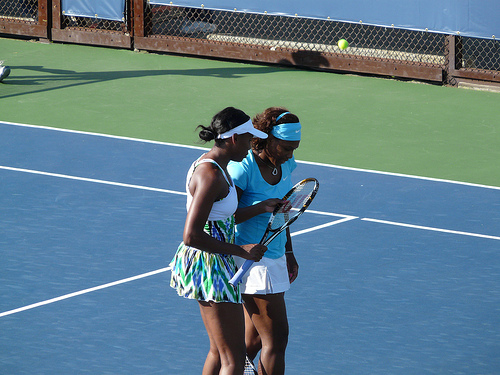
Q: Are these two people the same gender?
A: Yes, all the people are female.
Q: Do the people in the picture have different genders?
A: No, all the people are female.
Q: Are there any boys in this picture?
A: No, there are no boys.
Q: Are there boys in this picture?
A: No, there are no boys.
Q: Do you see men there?
A: No, there are no men.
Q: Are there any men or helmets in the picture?
A: No, there are no men or helmets.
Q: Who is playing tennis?
A: The player is playing tennis.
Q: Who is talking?
A: The player is talking.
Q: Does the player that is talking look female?
A: Yes, the player is female.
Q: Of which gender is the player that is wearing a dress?
A: The player is female.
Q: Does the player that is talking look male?
A: No, the player is female.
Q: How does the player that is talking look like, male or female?
A: The player is female.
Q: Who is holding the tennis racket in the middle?
A: The player is holding the racket.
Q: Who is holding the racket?
A: The player is holding the racket.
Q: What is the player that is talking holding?
A: The player is holding the racket.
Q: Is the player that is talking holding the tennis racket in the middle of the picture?
A: Yes, the player is holding the racket.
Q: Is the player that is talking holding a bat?
A: No, the player is holding the racket.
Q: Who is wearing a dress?
A: The player is wearing a dress.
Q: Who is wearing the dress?
A: The player is wearing a dress.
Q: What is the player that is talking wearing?
A: The player is wearing a dress.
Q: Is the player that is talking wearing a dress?
A: Yes, the player is wearing a dress.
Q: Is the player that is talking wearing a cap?
A: No, the player is wearing a dress.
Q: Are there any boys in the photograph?
A: No, there are no boys.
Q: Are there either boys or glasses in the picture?
A: No, there are no boys or glasses.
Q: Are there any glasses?
A: No, there are no glasses.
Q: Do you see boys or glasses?
A: No, there are no glasses or boys.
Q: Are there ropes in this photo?
A: No, there are no ropes.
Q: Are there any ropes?
A: No, there are no ropes.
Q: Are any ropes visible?
A: No, there are no ropes.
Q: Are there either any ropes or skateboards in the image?
A: No, there are no ropes or skateboards.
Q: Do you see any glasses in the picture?
A: No, there are no glasses.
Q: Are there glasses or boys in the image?
A: No, there are no glasses or boys.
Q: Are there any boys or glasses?
A: No, there are no glasses or boys.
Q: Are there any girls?
A: No, there are no girls.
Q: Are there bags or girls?
A: No, there are no girls or bags.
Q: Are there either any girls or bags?
A: No, there are no girls or bags.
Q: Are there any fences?
A: Yes, there is a fence.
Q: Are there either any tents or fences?
A: Yes, there is a fence.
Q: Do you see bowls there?
A: No, there are no bowls.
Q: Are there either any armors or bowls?
A: No, there are no bowls or armors.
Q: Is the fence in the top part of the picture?
A: Yes, the fence is in the top of the image.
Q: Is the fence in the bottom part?
A: No, the fence is in the top of the image.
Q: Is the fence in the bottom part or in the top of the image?
A: The fence is in the top of the image.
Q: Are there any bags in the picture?
A: No, there are no bags.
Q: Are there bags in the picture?
A: No, there are no bags.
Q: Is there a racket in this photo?
A: Yes, there is a racket.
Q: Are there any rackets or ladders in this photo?
A: Yes, there is a racket.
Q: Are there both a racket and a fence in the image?
A: Yes, there are both a racket and a fence.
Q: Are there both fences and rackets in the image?
A: Yes, there are both a racket and a fence.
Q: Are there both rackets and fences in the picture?
A: Yes, there are both a racket and a fence.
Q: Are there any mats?
A: No, there are no mats.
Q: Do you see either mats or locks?
A: No, there are no mats or locks.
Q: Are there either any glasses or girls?
A: No, there are no girls or glasses.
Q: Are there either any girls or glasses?
A: No, there are no girls or glasses.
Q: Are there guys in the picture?
A: No, there are no guys.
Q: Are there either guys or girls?
A: No, there are no guys or girls.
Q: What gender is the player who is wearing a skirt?
A: The player is female.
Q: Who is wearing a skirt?
A: The player is wearing a skirt.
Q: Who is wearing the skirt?
A: The player is wearing a skirt.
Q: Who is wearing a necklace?
A: The player is wearing a necklace.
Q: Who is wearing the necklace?
A: The player is wearing a necklace.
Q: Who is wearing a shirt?
A: The player is wearing a shirt.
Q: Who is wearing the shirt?
A: The player is wearing a shirt.